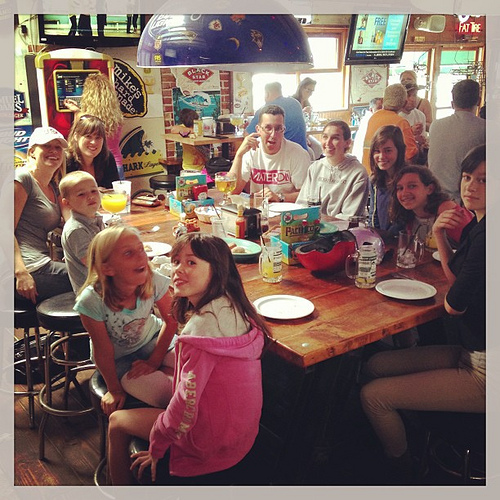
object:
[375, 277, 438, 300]
plate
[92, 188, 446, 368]
table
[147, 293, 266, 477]
jacket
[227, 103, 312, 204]
man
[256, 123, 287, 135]
glasses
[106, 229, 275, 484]
girl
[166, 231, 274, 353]
brown hair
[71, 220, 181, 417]
girl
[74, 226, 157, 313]
blonde hair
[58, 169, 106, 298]
boy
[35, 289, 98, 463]
barstool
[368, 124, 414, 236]
lady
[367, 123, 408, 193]
dark hair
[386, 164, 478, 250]
people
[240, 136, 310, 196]
shirt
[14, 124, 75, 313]
woman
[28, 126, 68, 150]
baseball cap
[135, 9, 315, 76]
light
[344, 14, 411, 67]
tv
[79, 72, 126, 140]
blonde hair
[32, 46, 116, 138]
juke box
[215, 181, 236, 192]
beer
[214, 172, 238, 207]
glass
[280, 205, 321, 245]
menu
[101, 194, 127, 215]
yellow drink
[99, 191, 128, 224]
glass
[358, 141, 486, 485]
female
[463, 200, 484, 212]
chin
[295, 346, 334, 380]
part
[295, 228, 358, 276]
red helmet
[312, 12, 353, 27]
wall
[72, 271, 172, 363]
blue shirt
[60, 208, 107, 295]
gray shirt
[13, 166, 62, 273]
gray shirt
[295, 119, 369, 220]
woman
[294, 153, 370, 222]
gray hoodie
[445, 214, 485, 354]
black shirt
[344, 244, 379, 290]
mug